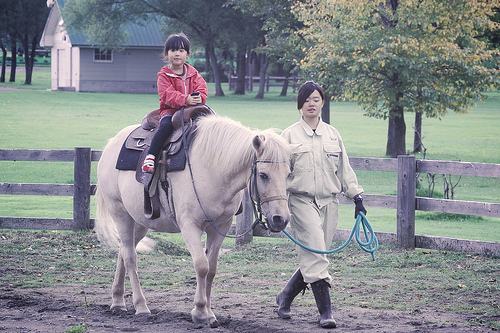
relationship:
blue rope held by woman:
[280, 210, 379, 261] [274, 71, 375, 331]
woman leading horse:
[274, 71, 375, 331] [92, 117, 291, 320]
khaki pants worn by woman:
[285, 196, 342, 288] [267, 76, 371, 306]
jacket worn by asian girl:
[155, 59, 210, 119] [136, 33, 208, 173]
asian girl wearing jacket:
[136, 33, 208, 173] [152, 60, 209, 107]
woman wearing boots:
[274, 71, 375, 331] [275, 267, 337, 329]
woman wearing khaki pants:
[274, 71, 375, 331] [285, 194, 344, 288]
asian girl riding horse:
[118, 27, 266, 182] [96, 128, 287, 323]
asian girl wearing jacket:
[136, 33, 208, 173] [150, 62, 212, 119]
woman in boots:
[274, 81, 367, 327] [262, 267, 342, 332]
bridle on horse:
[247, 146, 268, 229] [95, 112, 313, 328]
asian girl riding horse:
[136, 33, 208, 173] [92, 117, 291, 320]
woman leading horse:
[274, 71, 375, 331] [95, 112, 313, 328]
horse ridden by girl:
[96, 128, 287, 323] [143, 30, 214, 129]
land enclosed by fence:
[6, 38, 486, 317] [0, 155, 489, 254]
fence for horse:
[0, 155, 489, 254] [71, 48, 296, 320]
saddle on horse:
[126, 88, 213, 217] [92, 117, 291, 320]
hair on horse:
[189, 104, 287, 181] [66, 107, 297, 317]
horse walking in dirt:
[95, 112, 313, 328] [0, 228, 498, 329]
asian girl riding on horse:
[136, 33, 208, 173] [54, 96, 359, 328]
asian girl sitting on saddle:
[136, 33, 208, 173] [125, 106, 210, 220]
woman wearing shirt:
[274, 81, 367, 327] [277, 113, 365, 202]